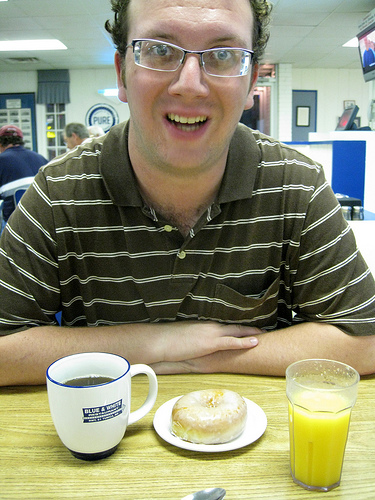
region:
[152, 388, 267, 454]
small plate with on doughnut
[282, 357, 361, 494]
glass with orange juice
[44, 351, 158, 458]
mug with coffee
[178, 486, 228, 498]
tip of silver spoon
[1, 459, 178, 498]
wooden table for sitting at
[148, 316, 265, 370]
folded hands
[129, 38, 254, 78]
glasses for vision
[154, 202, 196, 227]
chest hair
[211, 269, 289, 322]
breast pocket on green and white tee shirt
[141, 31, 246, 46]
eye brows of surprise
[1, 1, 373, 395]
A man in the foreground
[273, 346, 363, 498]
Orange juice in a glass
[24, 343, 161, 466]
A cup of coffee in the foreground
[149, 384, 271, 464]
A donut in the foreground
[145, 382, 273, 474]
Donut is on a white plate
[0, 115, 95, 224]
People in the background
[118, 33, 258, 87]
Person is wearing thin framed eyeglasses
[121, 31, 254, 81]
Man has blue colored eyes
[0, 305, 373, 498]
Man's arms are on the table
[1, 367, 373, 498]
The table is made of wood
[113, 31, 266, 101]
Man is wearing eyeglasses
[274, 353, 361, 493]
A glass in the foreground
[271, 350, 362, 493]
Orange juice is inside the glass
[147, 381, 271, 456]
A donut on a plate in the foreground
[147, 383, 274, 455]
The plate is white in color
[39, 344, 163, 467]
A white cup in the foreground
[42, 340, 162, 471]
Coffee is inside the cup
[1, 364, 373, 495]
A wooden table in the foreground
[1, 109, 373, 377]
Man is wearing a polo shirt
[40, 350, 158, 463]
white and blue mug of coffee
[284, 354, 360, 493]
full glass of orange juice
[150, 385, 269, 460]
glazed doughnut on small white plate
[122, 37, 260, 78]
pair of glasses on man's face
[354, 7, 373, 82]
tv hanging from ceiling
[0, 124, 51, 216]
man in red hat with back to camera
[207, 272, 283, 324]
pocket on front of man's shirt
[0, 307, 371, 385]
arms folded on a table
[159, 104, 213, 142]
man's smiling mouth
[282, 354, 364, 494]
A glass of orange juice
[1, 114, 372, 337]
White stripes on a shirt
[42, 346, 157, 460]
Coffee in a white mug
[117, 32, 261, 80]
Glasses over man's eyes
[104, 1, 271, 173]
A man is smiling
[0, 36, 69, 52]
A light on the ceiling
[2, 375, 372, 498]
A brown wooden table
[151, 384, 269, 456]
A donut on a plate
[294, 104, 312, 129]
A rectangular white sign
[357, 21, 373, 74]
A television screen is on